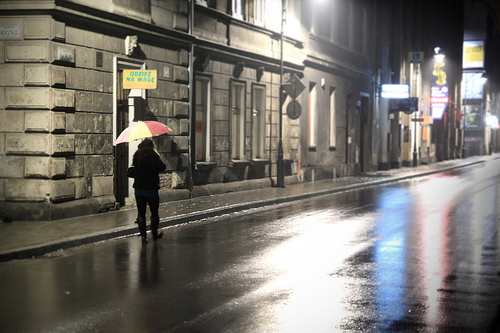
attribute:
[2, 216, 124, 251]
sidewalk — wet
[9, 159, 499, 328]
ground — wet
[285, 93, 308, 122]
sign — circular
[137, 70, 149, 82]
writing — green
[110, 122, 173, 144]
umbrella — red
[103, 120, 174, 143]
umbrella — red, yellow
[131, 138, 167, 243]
person — walking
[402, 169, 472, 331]
reflection — light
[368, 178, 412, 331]
reflection — light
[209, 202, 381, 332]
reflection — light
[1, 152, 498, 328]
street — wet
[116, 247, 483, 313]
pavement — wet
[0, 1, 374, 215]
building — tan, concrete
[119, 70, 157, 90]
sign — green, yellow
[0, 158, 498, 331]
pavement — wet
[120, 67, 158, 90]
sign — yellow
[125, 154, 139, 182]
handbag — black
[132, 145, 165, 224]
clothing — dark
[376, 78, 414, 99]
sign — lit